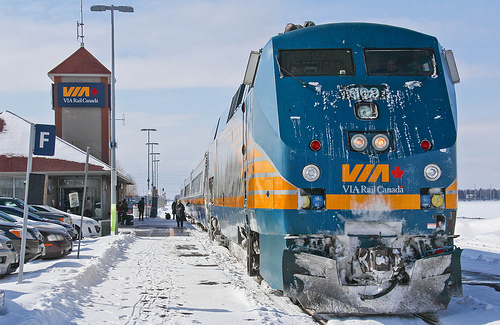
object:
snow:
[104, 252, 215, 321]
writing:
[341, 161, 408, 196]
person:
[135, 196, 147, 221]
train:
[175, 20, 464, 322]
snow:
[316, 79, 429, 104]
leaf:
[390, 164, 404, 181]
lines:
[323, 195, 422, 209]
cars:
[29, 203, 102, 238]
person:
[171, 199, 187, 230]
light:
[308, 136, 322, 153]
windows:
[275, 46, 356, 81]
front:
[266, 44, 455, 193]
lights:
[88, 2, 138, 20]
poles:
[88, 3, 139, 241]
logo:
[61, 86, 98, 98]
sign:
[58, 83, 107, 108]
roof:
[47, 44, 114, 80]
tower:
[46, 43, 119, 172]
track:
[123, 253, 201, 324]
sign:
[32, 123, 56, 159]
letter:
[38, 130, 49, 151]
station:
[0, 0, 135, 242]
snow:
[0, 106, 110, 168]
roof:
[0, 108, 134, 182]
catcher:
[287, 225, 463, 317]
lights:
[348, 135, 368, 152]